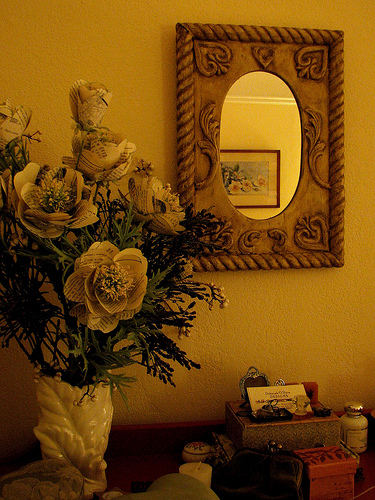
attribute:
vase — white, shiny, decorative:
[32, 369, 116, 499]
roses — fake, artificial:
[1, 79, 186, 334]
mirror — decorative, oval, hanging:
[175, 23, 345, 273]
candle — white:
[178, 460, 212, 489]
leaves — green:
[0, 116, 233, 413]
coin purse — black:
[212, 439, 305, 499]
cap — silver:
[344, 402, 363, 418]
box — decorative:
[292, 444, 357, 499]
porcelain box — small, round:
[183, 440, 211, 462]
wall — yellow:
[1, 0, 374, 460]